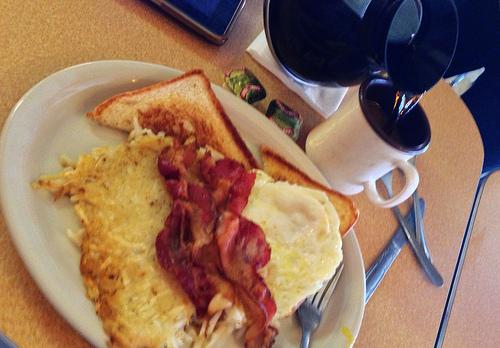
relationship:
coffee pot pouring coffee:
[261, 0, 461, 94] [389, 94, 422, 132]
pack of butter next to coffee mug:
[266, 100, 301, 145] [303, 77, 433, 209]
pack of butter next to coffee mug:
[221, 67, 268, 107] [303, 77, 433, 209]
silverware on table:
[368, 161, 443, 299] [0, 0, 500, 347]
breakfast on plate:
[58, 69, 360, 347] [2, 58, 366, 347]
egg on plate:
[249, 172, 343, 316] [2, 58, 366, 347]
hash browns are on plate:
[46, 132, 193, 347] [2, 58, 366, 347]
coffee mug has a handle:
[303, 77, 433, 209] [362, 161, 421, 208]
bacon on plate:
[157, 140, 220, 335] [2, 58, 366, 347]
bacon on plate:
[211, 155, 270, 347] [2, 58, 366, 347]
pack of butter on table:
[266, 100, 301, 145] [0, 0, 500, 347]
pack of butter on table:
[221, 67, 268, 107] [0, 0, 500, 347]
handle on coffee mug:
[362, 161, 421, 208] [303, 77, 433, 209]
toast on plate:
[89, 69, 256, 167] [2, 58, 366, 347]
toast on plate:
[262, 148, 358, 234] [2, 58, 366, 347]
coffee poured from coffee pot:
[389, 94, 422, 132] [261, 0, 461, 94]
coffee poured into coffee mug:
[389, 94, 422, 132] [303, 77, 433, 209]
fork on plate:
[297, 262, 344, 347] [2, 58, 366, 347]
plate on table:
[2, 58, 366, 347] [0, 0, 500, 347]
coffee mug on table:
[303, 77, 433, 209] [0, 0, 500, 347]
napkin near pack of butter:
[246, 31, 349, 119] [266, 100, 301, 145]